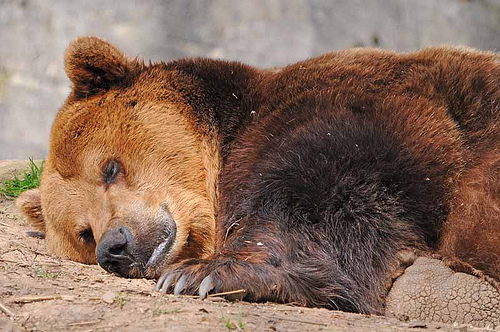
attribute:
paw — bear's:
[371, 242, 498, 329]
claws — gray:
[153, 270, 165, 293]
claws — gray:
[158, 269, 173, 293]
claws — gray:
[172, 270, 190, 297]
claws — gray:
[196, 270, 216, 297]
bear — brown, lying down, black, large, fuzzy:
[17, 35, 494, 310]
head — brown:
[39, 69, 230, 286]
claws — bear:
[163, 261, 281, 299]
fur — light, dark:
[144, 71, 462, 285]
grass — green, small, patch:
[1, 136, 68, 266]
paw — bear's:
[383, 251, 488, 330]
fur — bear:
[262, 107, 344, 182]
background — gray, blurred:
[6, 14, 494, 329]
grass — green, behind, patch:
[0, 156, 45, 199]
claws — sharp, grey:
[159, 266, 223, 300]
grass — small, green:
[9, 157, 45, 195]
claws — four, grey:
[149, 270, 219, 300]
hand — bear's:
[155, 253, 305, 307]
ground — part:
[24, 279, 134, 325]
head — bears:
[15, 37, 234, 259]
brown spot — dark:
[424, 60, 495, 155]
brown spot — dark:
[172, 58, 264, 143]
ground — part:
[35, 299, 115, 311]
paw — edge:
[151, 253, 262, 302]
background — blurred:
[2, 5, 490, 85]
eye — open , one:
[95, 154, 126, 192]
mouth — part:
[125, 200, 197, 278]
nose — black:
[84, 204, 152, 275]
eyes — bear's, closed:
[71, 145, 141, 246]